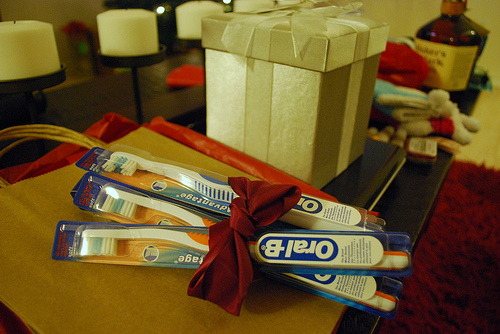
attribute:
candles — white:
[0, 2, 298, 91]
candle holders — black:
[7, 44, 212, 147]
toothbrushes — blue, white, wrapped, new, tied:
[49, 143, 415, 320]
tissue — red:
[134, 108, 344, 205]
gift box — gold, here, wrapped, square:
[197, 6, 392, 192]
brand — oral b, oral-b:
[257, 230, 336, 270]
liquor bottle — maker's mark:
[404, 4, 495, 107]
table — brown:
[11, 75, 496, 333]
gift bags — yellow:
[3, 129, 365, 333]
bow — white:
[217, 3, 370, 67]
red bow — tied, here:
[178, 172, 307, 321]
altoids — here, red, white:
[396, 134, 444, 167]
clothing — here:
[375, 37, 436, 95]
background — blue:
[52, 145, 109, 264]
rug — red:
[381, 160, 497, 330]